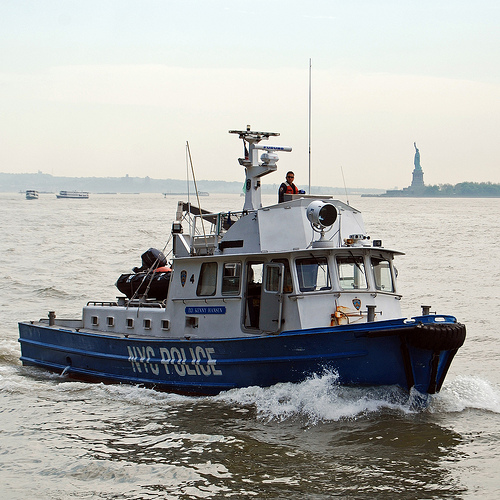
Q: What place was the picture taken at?
A: It was taken at the sea.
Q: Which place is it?
A: It is a sea.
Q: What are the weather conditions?
A: It is clear.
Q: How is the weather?
A: It is clear.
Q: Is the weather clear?
A: Yes, it is clear.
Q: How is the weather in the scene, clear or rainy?
A: It is clear.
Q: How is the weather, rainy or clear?
A: It is clear.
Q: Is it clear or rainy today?
A: It is clear.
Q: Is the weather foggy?
A: No, it is clear.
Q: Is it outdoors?
A: Yes, it is outdoors.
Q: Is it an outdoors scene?
A: Yes, it is outdoors.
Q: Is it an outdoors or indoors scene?
A: It is outdoors.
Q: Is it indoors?
A: No, it is outdoors.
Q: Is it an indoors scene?
A: No, it is outdoors.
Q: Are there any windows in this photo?
A: Yes, there is a window.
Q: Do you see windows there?
A: Yes, there is a window.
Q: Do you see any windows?
A: Yes, there is a window.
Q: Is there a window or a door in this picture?
A: Yes, there is a window.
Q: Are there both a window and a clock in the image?
A: No, there is a window but no clocks.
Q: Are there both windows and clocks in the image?
A: No, there is a window but no clocks.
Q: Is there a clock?
A: No, there are no clocks.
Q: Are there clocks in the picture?
A: No, there are no clocks.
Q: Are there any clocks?
A: No, there are no clocks.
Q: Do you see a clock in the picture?
A: No, there are no clocks.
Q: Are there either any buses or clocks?
A: No, there are no clocks or buses.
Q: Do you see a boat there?
A: Yes, there is a boat.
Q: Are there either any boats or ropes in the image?
A: Yes, there is a boat.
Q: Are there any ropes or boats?
A: Yes, there is a boat.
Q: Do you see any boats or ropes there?
A: Yes, there is a boat.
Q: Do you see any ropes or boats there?
A: Yes, there is a boat.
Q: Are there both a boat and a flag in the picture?
A: No, there is a boat but no flags.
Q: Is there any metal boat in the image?
A: Yes, there is a metal boat.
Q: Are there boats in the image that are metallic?
A: Yes, there is a boat that is metallic.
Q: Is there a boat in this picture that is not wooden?
A: Yes, there is a metallic boat.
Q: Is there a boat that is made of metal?
A: Yes, there is a boat that is made of metal.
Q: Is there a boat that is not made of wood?
A: Yes, there is a boat that is made of metal.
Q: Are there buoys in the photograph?
A: No, there are no buoys.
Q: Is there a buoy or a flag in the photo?
A: No, there are no buoys or flags.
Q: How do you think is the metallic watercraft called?
A: The watercraft is a boat.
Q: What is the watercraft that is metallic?
A: The watercraft is a boat.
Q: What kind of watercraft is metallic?
A: The watercraft is a boat.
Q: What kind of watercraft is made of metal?
A: The watercraft is a boat.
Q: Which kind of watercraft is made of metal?
A: The watercraft is a boat.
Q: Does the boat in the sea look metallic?
A: Yes, the boat is metallic.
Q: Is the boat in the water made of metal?
A: Yes, the boat is made of metal.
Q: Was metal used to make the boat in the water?
A: Yes, the boat is made of metal.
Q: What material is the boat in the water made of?
A: The boat is made of metal.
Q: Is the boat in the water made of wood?
A: No, the boat is made of metal.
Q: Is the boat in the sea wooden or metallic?
A: The boat is metallic.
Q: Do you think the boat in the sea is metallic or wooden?
A: The boat is metallic.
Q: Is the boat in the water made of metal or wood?
A: The boat is made of metal.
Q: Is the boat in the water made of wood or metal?
A: The boat is made of metal.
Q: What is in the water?
A: The boat is in the water.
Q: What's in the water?
A: The boat is in the water.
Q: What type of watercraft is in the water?
A: The watercraft is a boat.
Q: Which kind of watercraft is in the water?
A: The watercraft is a boat.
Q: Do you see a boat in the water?
A: Yes, there is a boat in the water.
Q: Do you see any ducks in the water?
A: No, there is a boat in the water.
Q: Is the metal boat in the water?
A: Yes, the boat is in the water.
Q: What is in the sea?
A: The boat is in the sea.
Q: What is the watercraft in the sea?
A: The watercraft is a boat.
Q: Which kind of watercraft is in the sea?
A: The watercraft is a boat.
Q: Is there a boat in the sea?
A: Yes, there is a boat in the sea.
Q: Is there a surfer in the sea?
A: No, there is a boat in the sea.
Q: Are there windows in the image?
A: Yes, there is a window.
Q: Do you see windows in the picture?
A: Yes, there is a window.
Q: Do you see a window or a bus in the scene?
A: Yes, there is a window.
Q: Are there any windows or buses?
A: Yes, there is a window.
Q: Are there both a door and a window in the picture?
A: Yes, there are both a window and a door.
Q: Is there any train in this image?
A: No, there are no trains.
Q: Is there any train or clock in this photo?
A: No, there are no trains or clocks.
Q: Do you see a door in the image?
A: Yes, there is a door.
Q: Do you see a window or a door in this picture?
A: Yes, there is a door.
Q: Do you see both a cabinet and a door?
A: No, there is a door but no cabinets.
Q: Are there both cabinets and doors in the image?
A: No, there is a door but no cabinets.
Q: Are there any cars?
A: No, there are no cars.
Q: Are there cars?
A: No, there are no cars.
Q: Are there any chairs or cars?
A: No, there are no cars or chairs.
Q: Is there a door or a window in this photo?
A: Yes, there is a window.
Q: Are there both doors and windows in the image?
A: Yes, there are both a window and a door.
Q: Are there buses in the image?
A: No, there are no buses.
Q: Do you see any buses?
A: No, there are no buses.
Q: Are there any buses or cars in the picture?
A: No, there are no buses or cars.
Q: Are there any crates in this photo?
A: No, there are no crates.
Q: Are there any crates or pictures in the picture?
A: No, there are no crates or pictures.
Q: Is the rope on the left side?
A: Yes, the rope is on the left of the image.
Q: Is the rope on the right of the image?
A: No, the rope is on the left of the image.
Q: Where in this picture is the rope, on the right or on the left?
A: The rope is on the left of the image.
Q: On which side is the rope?
A: The rope is on the left of the image.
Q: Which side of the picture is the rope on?
A: The rope is on the left of the image.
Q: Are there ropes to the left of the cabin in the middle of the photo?
A: Yes, there is a rope to the left of the cabin.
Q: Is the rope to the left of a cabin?
A: Yes, the rope is to the left of a cabin.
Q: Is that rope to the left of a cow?
A: No, the rope is to the left of a cabin.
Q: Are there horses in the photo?
A: No, there are no horses.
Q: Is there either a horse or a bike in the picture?
A: No, there are no horses or bikes.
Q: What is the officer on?
A: The officer is on the boat.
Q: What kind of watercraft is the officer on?
A: The officer is on the boat.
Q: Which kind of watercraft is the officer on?
A: The officer is on the boat.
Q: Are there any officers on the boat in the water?
A: Yes, there is an officer on the boat.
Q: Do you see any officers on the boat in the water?
A: Yes, there is an officer on the boat.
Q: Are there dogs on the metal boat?
A: No, there is an officer on the boat.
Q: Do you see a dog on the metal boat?
A: No, there is an officer on the boat.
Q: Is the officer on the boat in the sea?
A: Yes, the officer is on the boat.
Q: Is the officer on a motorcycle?
A: No, the officer is on the boat.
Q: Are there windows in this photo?
A: Yes, there is a window.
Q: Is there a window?
A: Yes, there is a window.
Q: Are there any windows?
A: Yes, there is a window.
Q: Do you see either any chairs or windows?
A: Yes, there is a window.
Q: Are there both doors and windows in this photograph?
A: Yes, there are both a window and doors.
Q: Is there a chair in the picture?
A: No, there are no chairs.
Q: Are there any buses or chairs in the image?
A: No, there are no chairs or buses.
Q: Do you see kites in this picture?
A: No, there are no kites.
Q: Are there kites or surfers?
A: No, there are no kites or surfers.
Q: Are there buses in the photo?
A: No, there are no buses.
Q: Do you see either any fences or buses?
A: No, there are no buses or fences.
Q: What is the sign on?
A: The sign is on the boat.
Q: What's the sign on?
A: The sign is on the boat.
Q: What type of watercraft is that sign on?
A: The sign is on the boat.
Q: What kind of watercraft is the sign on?
A: The sign is on the boat.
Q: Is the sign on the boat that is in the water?
A: Yes, the sign is on the boat.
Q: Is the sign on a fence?
A: No, the sign is on the boat.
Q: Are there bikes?
A: No, there are no bikes.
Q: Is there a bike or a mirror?
A: No, there are no bikes or mirrors.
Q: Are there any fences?
A: No, there are no fences.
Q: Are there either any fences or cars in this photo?
A: No, there are no fences or cars.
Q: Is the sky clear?
A: Yes, the sky is clear.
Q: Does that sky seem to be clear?
A: Yes, the sky is clear.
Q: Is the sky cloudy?
A: No, the sky is clear.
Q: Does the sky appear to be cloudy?
A: No, the sky is clear.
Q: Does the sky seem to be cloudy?
A: No, the sky is clear.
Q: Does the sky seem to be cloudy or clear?
A: The sky is clear.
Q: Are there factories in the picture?
A: No, there are no factories.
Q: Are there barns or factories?
A: No, there are no factories or barns.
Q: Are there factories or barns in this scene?
A: No, there are no factories or barns.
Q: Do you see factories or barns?
A: No, there are no factories or barns.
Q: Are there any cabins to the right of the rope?
A: Yes, there is a cabin to the right of the rope.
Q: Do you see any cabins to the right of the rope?
A: Yes, there is a cabin to the right of the rope.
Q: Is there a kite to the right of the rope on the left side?
A: No, there is a cabin to the right of the rope.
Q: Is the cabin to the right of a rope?
A: Yes, the cabin is to the right of a rope.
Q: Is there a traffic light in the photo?
A: No, there are no traffic lights.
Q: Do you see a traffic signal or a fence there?
A: No, there are no traffic lights or fences.